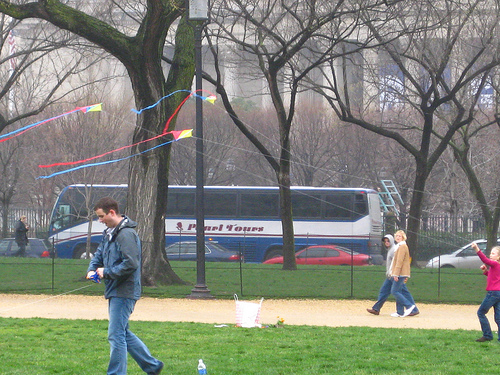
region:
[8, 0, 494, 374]
people flying kite in park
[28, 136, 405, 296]
bus outside of park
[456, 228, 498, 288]
girl wearing pink shirt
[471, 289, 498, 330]
girl wearing blue jeans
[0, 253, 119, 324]
man holding white string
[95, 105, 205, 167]
kite is red and yellow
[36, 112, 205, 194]
kite has blue and red tail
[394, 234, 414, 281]
woman wearing brown jacket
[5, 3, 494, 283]
trees without any leaves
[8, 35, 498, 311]
girl holding kite string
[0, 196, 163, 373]
A man is reeling in a kite line.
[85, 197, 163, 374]
A man wearing a blue and black coat.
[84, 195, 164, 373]
A man wearing blue jeans.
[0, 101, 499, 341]
A girl is flying a kite.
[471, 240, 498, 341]
A girl wearing a pink shirt.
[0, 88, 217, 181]
Three yellow, red and blue kites.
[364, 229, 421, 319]
Two people walking side-by-side.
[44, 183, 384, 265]
A blue and white bus.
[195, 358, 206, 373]
A bottle of water.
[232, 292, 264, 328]
A white hand bag.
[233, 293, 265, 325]
white bag on the grass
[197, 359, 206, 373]
plastic water bottle with a blue label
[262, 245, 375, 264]
red car on the curb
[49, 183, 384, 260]
large blue and white bus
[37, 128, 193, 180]
colorful kite with long tail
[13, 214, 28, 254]
person in black walking in the distance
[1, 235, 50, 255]
black hatchback at the curb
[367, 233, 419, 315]
person walking in a gray hoodie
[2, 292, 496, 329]
brown walking area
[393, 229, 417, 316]
person in a brown coat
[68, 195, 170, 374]
person wearing a wind coat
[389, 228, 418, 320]
person wearing a pair of shoes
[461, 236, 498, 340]
kid wearing a pink shirt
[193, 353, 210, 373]
bottle on a grass field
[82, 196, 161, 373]
person wearing a blue jean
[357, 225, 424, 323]
couple walking in the park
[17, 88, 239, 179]
kites in mid air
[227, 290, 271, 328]
a bag on the floor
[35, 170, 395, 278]
tour bus passing by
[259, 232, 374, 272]
car parked on street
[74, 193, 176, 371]
man in blue clothes flying kite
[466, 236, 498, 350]
girl in pink sweater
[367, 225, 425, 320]
pedestrians walking through park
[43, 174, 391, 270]
blue and white city buss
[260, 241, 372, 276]
red car parked on street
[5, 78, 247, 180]
kites flying in the breeze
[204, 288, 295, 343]
basket on the lawn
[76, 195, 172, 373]
man in blue jacket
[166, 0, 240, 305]
lamppost in the park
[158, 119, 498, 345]
little girl flying a kite